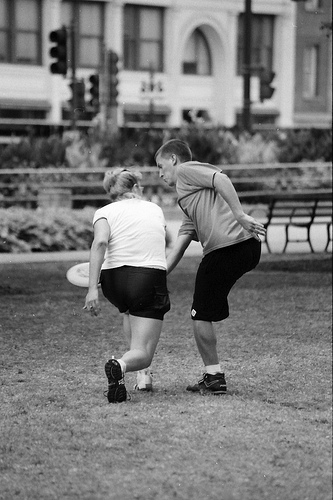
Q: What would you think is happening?
A: Man and woman play frisbee.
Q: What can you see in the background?
A: Street lights.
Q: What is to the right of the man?
A: Bench.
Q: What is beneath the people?
A: Grass.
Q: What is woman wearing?
A: Shorts.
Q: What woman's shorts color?
A: Black.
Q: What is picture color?
A: Black and white.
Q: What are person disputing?
A: Frisbee.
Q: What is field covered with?
A: Grass.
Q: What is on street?
A: Traffic light.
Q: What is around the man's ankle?
A: Sock.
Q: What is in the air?
A: Frisbee.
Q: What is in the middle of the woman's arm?
A: Elbow.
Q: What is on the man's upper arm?
A: Shirt sleeve.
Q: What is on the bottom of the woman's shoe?
A: Cleats.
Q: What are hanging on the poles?
A: Lights.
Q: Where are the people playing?
A: Field.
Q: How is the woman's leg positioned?
A: Bent.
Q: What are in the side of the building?
A: Windows.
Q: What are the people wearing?
A: Shorts.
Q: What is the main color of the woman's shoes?
A: Black.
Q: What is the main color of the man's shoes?
A: Black.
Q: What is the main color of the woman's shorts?
A: Black.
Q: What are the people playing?
A: Frisbee.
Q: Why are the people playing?
A: To have fun.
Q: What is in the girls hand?
A: Frisbee.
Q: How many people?
A: 2.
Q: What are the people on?
A: The grass.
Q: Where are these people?
A: Park.